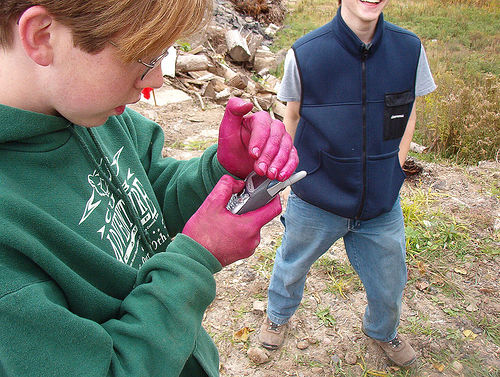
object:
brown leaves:
[462, 330, 479, 341]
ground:
[124, 0, 499, 376]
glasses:
[105, 39, 170, 81]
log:
[224, 30, 250, 61]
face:
[55, 27, 182, 126]